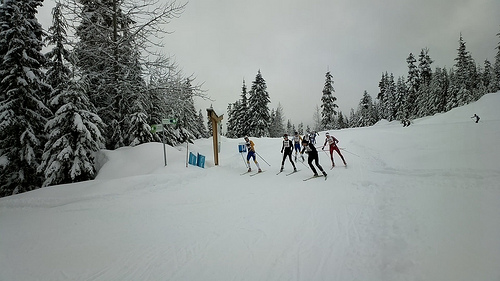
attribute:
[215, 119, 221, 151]
sign — wooden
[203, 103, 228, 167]
marker — wooden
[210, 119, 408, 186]
speeds — deadly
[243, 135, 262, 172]
skier — yellow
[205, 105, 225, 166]
sign — wooden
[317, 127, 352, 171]
skier — red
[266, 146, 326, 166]
tag — racing, identification, number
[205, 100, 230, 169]
sign — tall 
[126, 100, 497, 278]
hillside — snowy 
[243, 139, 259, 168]
suit — yellow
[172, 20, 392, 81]
sky — gray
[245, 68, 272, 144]
tree — snow, covered, pine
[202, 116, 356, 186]
ground — covered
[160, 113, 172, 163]
pole — silver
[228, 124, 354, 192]
skiers — group, cross country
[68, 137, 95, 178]
branches — tree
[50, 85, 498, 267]
snow — thick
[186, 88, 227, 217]
markers — trail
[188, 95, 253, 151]
marker — flag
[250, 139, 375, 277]
slope — ski